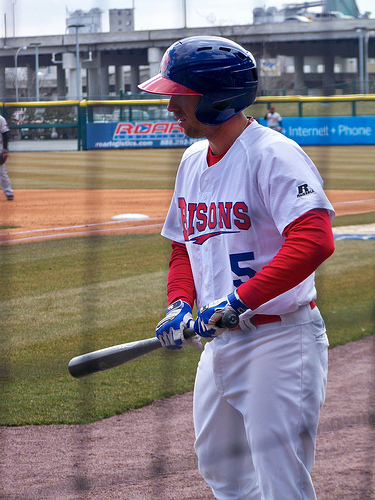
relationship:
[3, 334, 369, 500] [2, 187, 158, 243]
dirt near box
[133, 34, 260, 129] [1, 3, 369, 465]
helmet for outfield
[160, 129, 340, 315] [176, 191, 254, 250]
jersey says bisons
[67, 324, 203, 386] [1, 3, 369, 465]
club for outfield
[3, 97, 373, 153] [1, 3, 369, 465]
fence for outfield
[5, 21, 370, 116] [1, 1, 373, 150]
deck in background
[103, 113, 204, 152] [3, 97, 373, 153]
advertisement on fence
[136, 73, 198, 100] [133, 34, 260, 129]
part of helmet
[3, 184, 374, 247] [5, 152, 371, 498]
part of ground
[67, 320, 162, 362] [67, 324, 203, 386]
edge of club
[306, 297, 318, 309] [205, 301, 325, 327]
part of belt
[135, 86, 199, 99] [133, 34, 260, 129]
edge of helmet